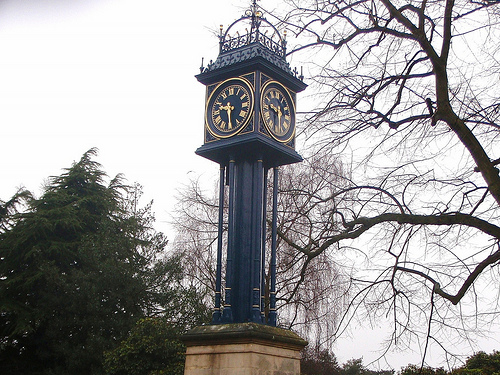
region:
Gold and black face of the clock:
[204, 79, 251, 133]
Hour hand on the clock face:
[218, 105, 234, 110]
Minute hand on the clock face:
[225, 103, 234, 130]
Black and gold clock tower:
[193, 6, 308, 327]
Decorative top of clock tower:
[198, 32, 305, 90]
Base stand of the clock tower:
[181, 321, 308, 373]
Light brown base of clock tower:
[181, 346, 301, 372]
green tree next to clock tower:
[2, 144, 189, 374]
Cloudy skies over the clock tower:
[17, 12, 181, 140]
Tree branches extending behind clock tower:
[185, 164, 440, 306]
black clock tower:
[188, 3, 328, 333]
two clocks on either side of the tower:
[197, 67, 299, 152]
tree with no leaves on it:
[165, 5, 491, 373]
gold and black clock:
[261, 79, 299, 141]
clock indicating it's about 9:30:
[205, 78, 250, 143]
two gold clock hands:
[266, 98, 287, 134]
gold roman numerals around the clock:
[206, 85, 253, 135]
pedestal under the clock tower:
[167, 308, 318, 374]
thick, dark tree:
[0, 142, 196, 374]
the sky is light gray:
[0, 0, 495, 368]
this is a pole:
[194, 23, 304, 327]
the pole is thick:
[217, 162, 275, 302]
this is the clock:
[207, 71, 254, 135]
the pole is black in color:
[216, 169, 278, 320]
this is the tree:
[379, 85, 488, 261]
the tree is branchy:
[351, 7, 484, 262]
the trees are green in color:
[19, 192, 135, 366]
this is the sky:
[9, 14, 174, 133]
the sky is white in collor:
[17, 12, 162, 138]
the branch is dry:
[318, 10, 453, 137]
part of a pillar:
[233, 232, 253, 268]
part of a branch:
[381, 150, 410, 184]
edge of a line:
[233, 318, 262, 348]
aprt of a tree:
[70, 197, 115, 262]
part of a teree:
[315, 188, 384, 271]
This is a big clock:
[258, 67, 297, 144]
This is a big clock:
[208, 76, 272, 144]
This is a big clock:
[263, 65, 313, 157]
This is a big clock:
[205, 67, 256, 147]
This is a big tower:
[194, 5, 319, 342]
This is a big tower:
[200, 2, 322, 354]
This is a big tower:
[197, 2, 313, 358]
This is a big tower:
[188, 5, 316, 344]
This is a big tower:
[203, 7, 329, 367]